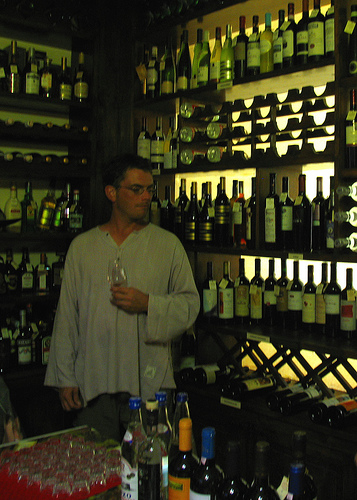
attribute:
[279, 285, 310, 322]
label — white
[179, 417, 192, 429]
cap — orange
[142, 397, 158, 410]
cap — yellow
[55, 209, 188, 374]
shirt — tan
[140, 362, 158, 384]
tag — white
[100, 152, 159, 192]
hair — dark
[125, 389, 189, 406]
caps — blue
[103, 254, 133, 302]
glass — empty